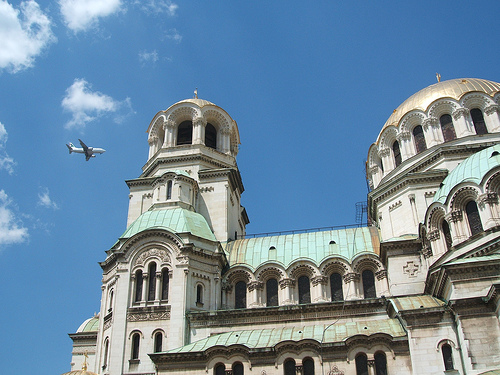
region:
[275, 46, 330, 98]
part of the sky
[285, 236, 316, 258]
part of a roof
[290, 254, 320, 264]
edge of a roof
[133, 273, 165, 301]
part of some window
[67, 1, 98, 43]
part of a cloud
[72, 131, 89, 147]
right wing of a plane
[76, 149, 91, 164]
part of a left wing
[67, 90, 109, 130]
part of a cloud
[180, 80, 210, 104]
tip of the building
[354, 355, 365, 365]
part of a window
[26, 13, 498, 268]
Picture is taken outside.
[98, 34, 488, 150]
Picture taken during the day.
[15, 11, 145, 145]
Small white clouds in the sky.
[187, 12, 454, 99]
The sky is blue in color.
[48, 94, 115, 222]
A plane is in the sky.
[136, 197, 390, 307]
The roof of the building is light green.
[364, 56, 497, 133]
The roof of the building is gold color.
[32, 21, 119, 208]
The plane is to the left of the building.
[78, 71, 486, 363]
The building has many windows.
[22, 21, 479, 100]
The sun is out.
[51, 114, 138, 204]
Commercial aircraft in the sky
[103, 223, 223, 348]
windows in the building.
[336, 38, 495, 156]
dome on the building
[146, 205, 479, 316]
tarnished copper on the roof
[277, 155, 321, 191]
blue sky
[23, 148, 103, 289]
some clouds in the blue sky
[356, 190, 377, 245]
a ladder on the top of the building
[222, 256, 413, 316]
arches above the windows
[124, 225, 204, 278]
ornate decorations above the doors and windows in the building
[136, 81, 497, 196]
Large building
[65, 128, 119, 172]
airplane in the blue sky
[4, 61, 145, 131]
the sky is blue with clouds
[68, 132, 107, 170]
the airplane is white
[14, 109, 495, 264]
the airplane is flying over building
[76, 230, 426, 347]
the building has windows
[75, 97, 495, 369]
the building is made of stone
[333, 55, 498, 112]
the building has a gold dome roof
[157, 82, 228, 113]
the small tower of building has gold roof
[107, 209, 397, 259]
the roof of the building is green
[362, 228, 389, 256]
the roof is rusty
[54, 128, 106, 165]
Plane flying in the sky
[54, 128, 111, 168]
Plane flying close to a building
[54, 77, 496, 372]
Building is tan and green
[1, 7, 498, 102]
Sky is blue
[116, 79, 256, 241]
Building has small tower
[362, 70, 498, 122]
Dome of tower is gold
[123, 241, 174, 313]
Arch window in front of building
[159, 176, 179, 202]
Narrow window on tower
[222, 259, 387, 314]
Five narrow windows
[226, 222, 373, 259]
Roof is turquoise